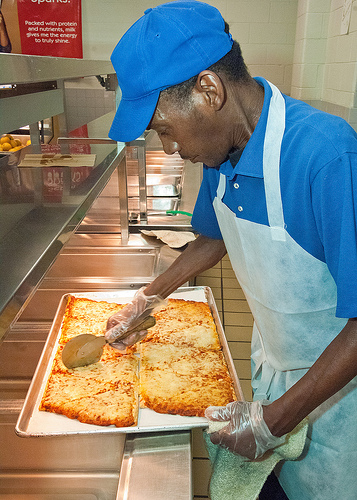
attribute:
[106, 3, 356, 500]
man — black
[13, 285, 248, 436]
tray — silver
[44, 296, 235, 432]
pizza — triangular, sliced, cheesy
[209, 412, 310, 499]
towel — dirty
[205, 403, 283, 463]
glove — transparent, plastic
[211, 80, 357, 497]
apron — white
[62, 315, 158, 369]
cutter — round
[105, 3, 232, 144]
hat — blue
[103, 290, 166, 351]
glove — transparent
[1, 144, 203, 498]
counter — steel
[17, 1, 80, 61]
sign — red